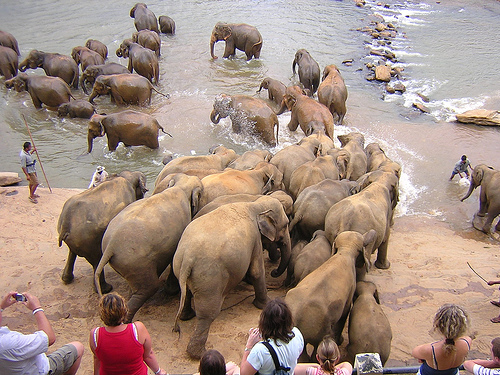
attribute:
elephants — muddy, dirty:
[156, 174, 345, 284]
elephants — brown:
[3, 2, 354, 149]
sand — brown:
[7, 216, 50, 269]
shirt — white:
[244, 324, 313, 373]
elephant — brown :
[6, 3, 496, 363]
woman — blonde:
[412, 303, 487, 374]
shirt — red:
[88, 320, 152, 374]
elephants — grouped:
[53, 130, 403, 357]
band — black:
[439, 307, 457, 311]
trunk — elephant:
[209, 38, 216, 64]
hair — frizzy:
[433, 306, 470, 337]